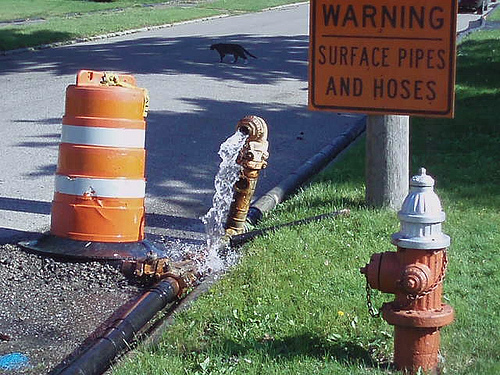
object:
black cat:
[209, 42, 257, 64]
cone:
[21, 67, 159, 261]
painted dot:
[0, 350, 32, 372]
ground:
[345, 147, 445, 222]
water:
[200, 133, 248, 265]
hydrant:
[357, 163, 458, 375]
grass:
[106, 2, 500, 375]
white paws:
[243, 59, 249, 64]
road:
[0, 0, 492, 375]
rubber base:
[15, 230, 166, 261]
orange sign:
[304, 0, 460, 115]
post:
[366, 113, 412, 211]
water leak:
[196, 108, 275, 268]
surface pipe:
[44, 268, 188, 375]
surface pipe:
[253, 114, 370, 217]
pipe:
[221, 115, 271, 234]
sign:
[280, 6, 472, 108]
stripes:
[47, 123, 151, 197]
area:
[0, 0, 499, 374]